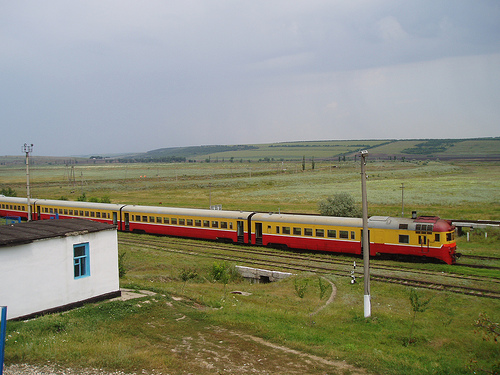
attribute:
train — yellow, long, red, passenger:
[226, 165, 472, 282]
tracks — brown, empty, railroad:
[383, 248, 483, 311]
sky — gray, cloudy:
[133, 19, 384, 119]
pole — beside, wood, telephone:
[346, 135, 383, 307]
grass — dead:
[161, 239, 260, 294]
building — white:
[5, 240, 93, 307]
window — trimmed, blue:
[65, 226, 109, 280]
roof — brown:
[1, 213, 93, 247]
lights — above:
[351, 137, 398, 170]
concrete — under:
[395, 252, 454, 278]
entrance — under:
[229, 263, 286, 291]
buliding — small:
[13, 210, 135, 285]